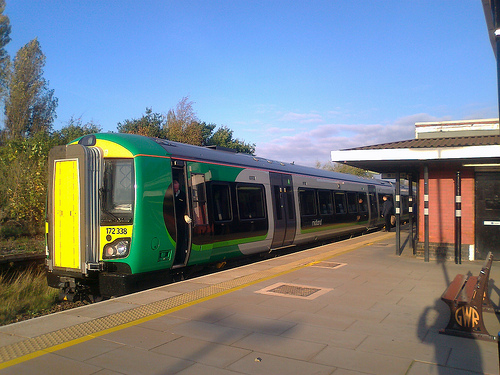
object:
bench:
[438, 251, 499, 343]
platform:
[334, 229, 417, 255]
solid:
[124, 291, 185, 324]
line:
[143, 293, 211, 324]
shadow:
[417, 241, 483, 373]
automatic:
[268, 171, 298, 249]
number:
[106, 227, 127, 235]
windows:
[204, 179, 268, 224]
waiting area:
[365, 155, 499, 375]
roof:
[330, 116, 500, 173]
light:
[101, 236, 132, 260]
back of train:
[45, 128, 417, 301]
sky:
[0, 0, 500, 150]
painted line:
[253, 281, 335, 301]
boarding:
[414, 164, 499, 262]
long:
[0, 232, 388, 372]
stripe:
[0, 295, 250, 375]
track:
[42, 133, 417, 307]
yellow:
[53, 161, 80, 269]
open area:
[0, 230, 500, 375]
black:
[147, 136, 395, 187]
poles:
[411, 165, 480, 270]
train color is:
[40, 131, 371, 274]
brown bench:
[437, 250, 499, 345]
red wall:
[415, 172, 475, 246]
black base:
[421, 166, 430, 262]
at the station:
[0, 117, 499, 373]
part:
[41, 134, 189, 300]